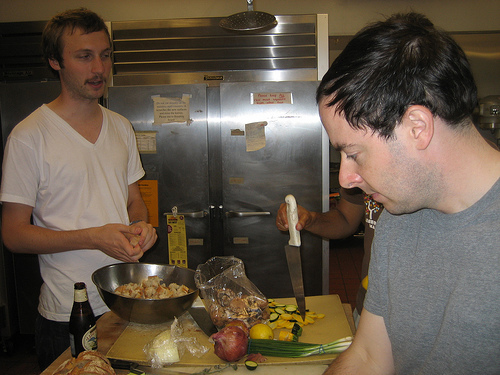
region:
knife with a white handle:
[275, 190, 311, 325]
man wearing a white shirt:
[1, 5, 158, 325]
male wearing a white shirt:
[4, 7, 157, 322]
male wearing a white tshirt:
[0, 4, 156, 324]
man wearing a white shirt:
[2, 7, 159, 332]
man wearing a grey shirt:
[311, 5, 497, 370]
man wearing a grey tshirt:
[315, 10, 497, 370]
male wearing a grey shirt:
[305, 10, 495, 370]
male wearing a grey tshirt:
[317, 11, 496, 373]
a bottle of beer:
[68, 280, 102, 355]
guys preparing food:
[10, 9, 493, 371]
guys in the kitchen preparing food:
[1, 8, 498, 372]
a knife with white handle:
[281, 193, 306, 321]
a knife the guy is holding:
[282, 194, 307, 322]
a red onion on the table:
[210, 325, 248, 362]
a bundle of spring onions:
[250, 334, 352, 359]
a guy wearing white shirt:
[3, 8, 158, 260]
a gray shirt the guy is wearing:
[361, 210, 494, 371]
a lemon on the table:
[248, 323, 274, 340]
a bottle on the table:
[67, 280, 97, 350]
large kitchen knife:
[283, 194, 308, 317]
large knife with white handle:
[282, 194, 307, 318]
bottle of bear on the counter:
[69, 280, 96, 354]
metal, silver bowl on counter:
[92, 263, 196, 323]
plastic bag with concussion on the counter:
[197, 258, 265, 321]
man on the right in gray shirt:
[316, 12, 497, 374]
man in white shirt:
[3, 11, 158, 363]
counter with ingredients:
[43, 297, 353, 372]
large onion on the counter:
[212, 327, 244, 360]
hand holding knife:
[278, 201, 358, 235]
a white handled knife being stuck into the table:
[270, 193, 325, 330]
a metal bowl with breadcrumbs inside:
[95, 257, 205, 322]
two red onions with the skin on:
[208, 318, 252, 365]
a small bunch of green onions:
[248, 328, 336, 360]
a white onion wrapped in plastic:
[143, 323, 192, 367]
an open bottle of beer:
[61, 279, 104, 360]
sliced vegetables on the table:
[266, 300, 326, 329]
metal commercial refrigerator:
[130, 70, 326, 295]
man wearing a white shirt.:
[5, 4, 165, 332]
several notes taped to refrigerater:
[135, 90, 295, 275]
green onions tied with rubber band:
[245, 335, 350, 355]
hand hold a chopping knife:
[271, 190, 311, 320]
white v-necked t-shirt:
[0, 100, 145, 320]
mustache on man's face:
[81, 73, 109, 87]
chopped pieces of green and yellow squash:
[263, 296, 327, 342]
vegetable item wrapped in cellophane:
[141, 313, 211, 370]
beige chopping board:
[102, 288, 361, 368]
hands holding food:
[98, 218, 159, 264]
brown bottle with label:
[66, 279, 101, 358]